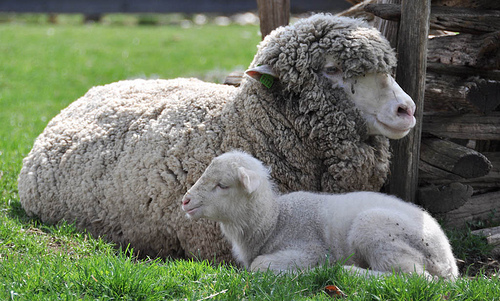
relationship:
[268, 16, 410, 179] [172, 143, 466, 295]
sheep next baby lamb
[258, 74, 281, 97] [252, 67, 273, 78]
tag in ear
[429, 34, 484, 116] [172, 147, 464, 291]
wood next to baby lamb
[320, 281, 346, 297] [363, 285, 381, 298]
leaf on grass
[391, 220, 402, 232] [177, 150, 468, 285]
spot on lamb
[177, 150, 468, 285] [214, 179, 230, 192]
lamb with closed eye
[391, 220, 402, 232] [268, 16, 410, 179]
spot on sheep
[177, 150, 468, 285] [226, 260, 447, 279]
lamb laying down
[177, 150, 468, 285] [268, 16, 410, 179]
lamb laying by lamb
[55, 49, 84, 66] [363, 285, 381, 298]
patch of grass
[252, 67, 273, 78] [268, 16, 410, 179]
ear tag of sheep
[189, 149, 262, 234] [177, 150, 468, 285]
head of lamb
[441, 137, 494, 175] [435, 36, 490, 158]
pile of logs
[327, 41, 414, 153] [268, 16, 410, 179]
face of a sheep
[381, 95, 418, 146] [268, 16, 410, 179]
muzzle of sheep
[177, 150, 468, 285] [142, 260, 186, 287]
lamb laying on field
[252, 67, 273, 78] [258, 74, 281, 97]
ear has tag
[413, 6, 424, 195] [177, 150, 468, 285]
structure next to lamb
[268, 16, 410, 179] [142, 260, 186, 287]
sheep graze in field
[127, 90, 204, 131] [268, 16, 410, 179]
wool on back of sheep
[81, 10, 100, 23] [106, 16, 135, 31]
cow in distance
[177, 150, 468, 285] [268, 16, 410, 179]
lamb lays beside sheep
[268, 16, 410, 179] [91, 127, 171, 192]
sheep with coat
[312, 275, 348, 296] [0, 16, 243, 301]
leaf on field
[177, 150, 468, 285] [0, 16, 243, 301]
lamb on field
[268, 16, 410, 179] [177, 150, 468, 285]
sheep behind lamb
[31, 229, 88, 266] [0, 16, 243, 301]
dirt in field